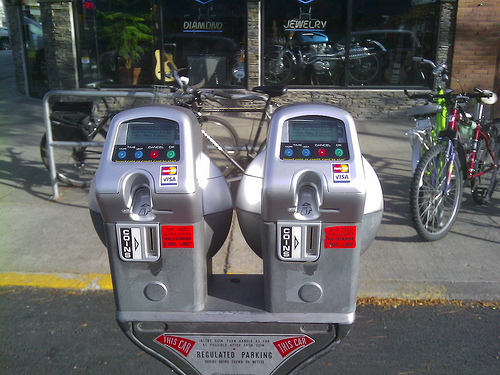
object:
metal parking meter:
[235, 101, 387, 314]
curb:
[2, 357, 500, 374]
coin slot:
[306, 226, 317, 252]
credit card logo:
[331, 162, 351, 183]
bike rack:
[39, 87, 244, 190]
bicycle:
[142, 73, 290, 180]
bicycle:
[401, 87, 498, 240]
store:
[2, 2, 499, 122]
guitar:
[154, 46, 180, 82]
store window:
[74, 2, 248, 88]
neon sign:
[282, 16, 327, 31]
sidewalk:
[2, 47, 500, 301]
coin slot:
[147, 226, 158, 254]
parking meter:
[88, 101, 235, 315]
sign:
[154, 332, 317, 375]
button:
[118, 150, 127, 157]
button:
[135, 150, 144, 158]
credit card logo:
[159, 164, 180, 186]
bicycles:
[399, 52, 483, 182]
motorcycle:
[263, 24, 388, 88]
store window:
[261, 1, 441, 89]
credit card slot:
[287, 186, 338, 220]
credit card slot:
[120, 205, 175, 221]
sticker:
[162, 225, 194, 248]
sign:
[324, 225, 357, 248]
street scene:
[0, 2, 499, 374]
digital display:
[289, 119, 338, 145]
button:
[149, 151, 158, 158]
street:
[1, 285, 498, 375]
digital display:
[126, 122, 175, 144]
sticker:
[120, 227, 143, 260]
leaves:
[393, 301, 405, 308]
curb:
[2, 273, 499, 311]